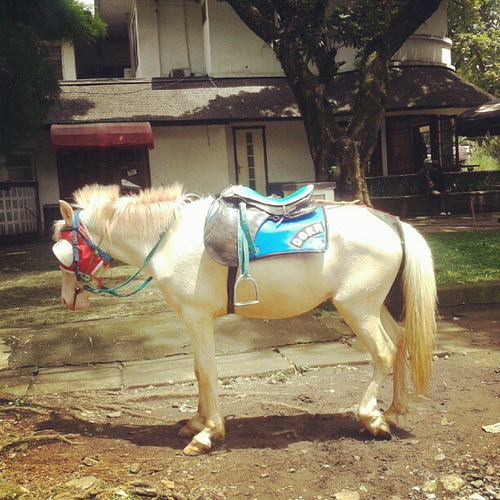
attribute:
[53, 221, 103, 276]
material — red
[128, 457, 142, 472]
rock — small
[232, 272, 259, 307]
stirrup — white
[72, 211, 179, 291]
rein — blue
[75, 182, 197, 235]
mane — white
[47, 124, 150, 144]
awning — red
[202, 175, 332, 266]
saddle — blue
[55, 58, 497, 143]
roof — black, decaying 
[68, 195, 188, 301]
harness — blue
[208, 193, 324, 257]
blanket — blue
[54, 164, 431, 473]
horse — white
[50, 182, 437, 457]
horse — white